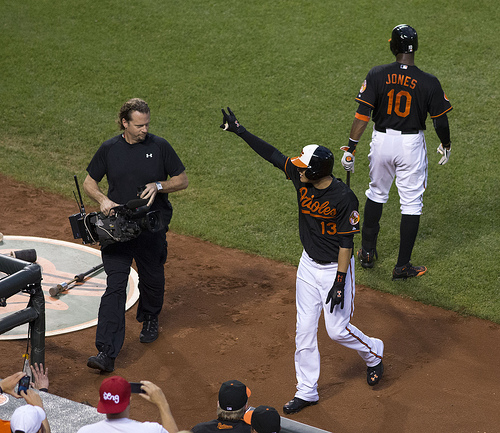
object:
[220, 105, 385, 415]
baseball player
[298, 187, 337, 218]
logo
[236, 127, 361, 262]
jersey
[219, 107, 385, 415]
man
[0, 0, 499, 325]
baseball field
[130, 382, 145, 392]
camera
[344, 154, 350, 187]
bat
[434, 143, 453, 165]
glove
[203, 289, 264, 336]
dirt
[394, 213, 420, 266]
socks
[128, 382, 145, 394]
phone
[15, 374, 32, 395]
blue cellphone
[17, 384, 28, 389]
black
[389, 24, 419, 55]
cap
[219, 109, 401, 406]
uniform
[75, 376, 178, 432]
man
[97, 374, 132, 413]
cap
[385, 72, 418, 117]
elephant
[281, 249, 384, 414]
pants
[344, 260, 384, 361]
stripes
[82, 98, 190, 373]
cameraman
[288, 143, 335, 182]
cap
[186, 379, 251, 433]
player's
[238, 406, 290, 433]
player's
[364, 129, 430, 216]
pants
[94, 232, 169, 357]
pants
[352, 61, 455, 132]
shirt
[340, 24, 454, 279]
man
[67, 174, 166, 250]
camera